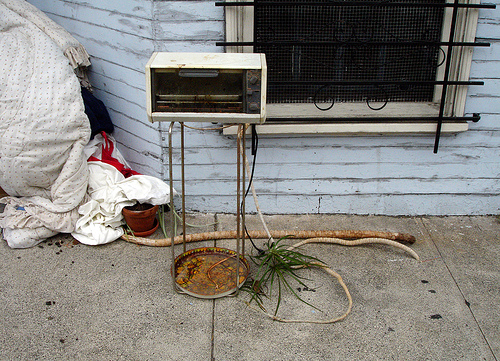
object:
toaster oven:
[146, 51, 269, 125]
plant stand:
[168, 121, 251, 300]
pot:
[123, 203, 160, 236]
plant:
[248, 234, 329, 321]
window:
[225, 2, 480, 137]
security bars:
[214, 32, 498, 58]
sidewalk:
[1, 212, 498, 360]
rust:
[236, 124, 248, 176]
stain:
[430, 313, 442, 321]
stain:
[427, 287, 436, 294]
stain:
[420, 276, 429, 285]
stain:
[386, 326, 395, 334]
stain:
[60, 337, 66, 344]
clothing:
[2, 2, 96, 237]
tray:
[170, 245, 252, 299]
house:
[26, 0, 500, 219]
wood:
[119, 228, 416, 248]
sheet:
[156, 85, 243, 102]